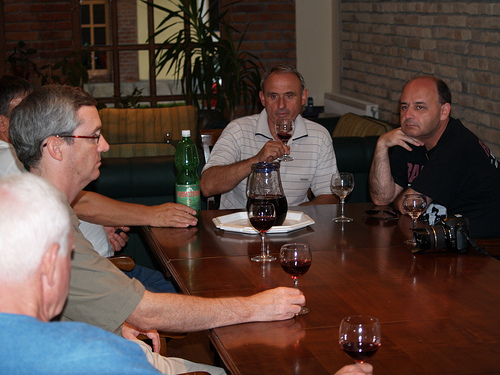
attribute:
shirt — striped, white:
[220, 104, 357, 215]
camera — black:
[407, 208, 498, 270]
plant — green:
[140, 0, 297, 100]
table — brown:
[146, 211, 498, 338]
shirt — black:
[390, 124, 499, 241]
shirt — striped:
[198, 107, 343, 217]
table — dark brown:
[147, 192, 499, 370]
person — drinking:
[170, 54, 378, 222]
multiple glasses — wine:
[238, 162, 473, 365]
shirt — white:
[204, 109, 343, 208]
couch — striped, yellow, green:
[109, 102, 201, 154]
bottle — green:
[175, 127, 202, 217]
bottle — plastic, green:
[171, 127, 206, 223]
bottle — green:
[165, 129, 206, 231]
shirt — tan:
[69, 237, 142, 331]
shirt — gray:
[19, 168, 145, 337]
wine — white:
[330, 181, 355, 200]